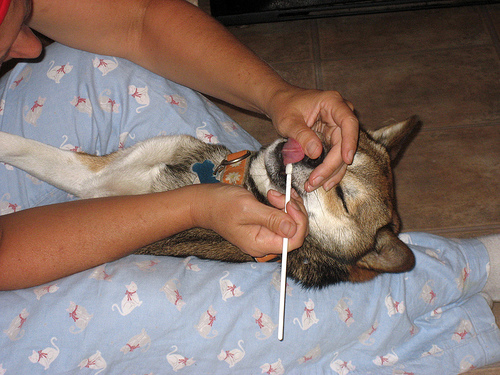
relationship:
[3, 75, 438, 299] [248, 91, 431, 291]
dog has head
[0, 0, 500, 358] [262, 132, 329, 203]
person cleaning teeth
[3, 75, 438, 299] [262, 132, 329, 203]
dog has teeth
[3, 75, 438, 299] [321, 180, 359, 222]
dog has eye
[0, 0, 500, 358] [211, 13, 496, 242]
person on top of floor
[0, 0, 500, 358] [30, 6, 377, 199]
person has hand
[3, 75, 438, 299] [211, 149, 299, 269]
dog has neck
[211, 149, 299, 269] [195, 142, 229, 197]
neck has dog tag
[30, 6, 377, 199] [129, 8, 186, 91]
arm has crease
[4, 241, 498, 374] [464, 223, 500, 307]
leg has sock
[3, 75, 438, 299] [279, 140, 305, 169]
dog has tounge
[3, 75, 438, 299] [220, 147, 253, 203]
dog has collar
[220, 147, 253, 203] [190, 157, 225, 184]
collar has dog tag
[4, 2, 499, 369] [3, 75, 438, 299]
person holding dog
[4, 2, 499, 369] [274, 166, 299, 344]
person holding q-tip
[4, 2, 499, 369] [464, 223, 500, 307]
person wearing sock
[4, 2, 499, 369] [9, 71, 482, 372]
person wearing pajama pants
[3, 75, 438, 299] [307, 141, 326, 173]
dog has nose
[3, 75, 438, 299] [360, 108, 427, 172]
dog has ear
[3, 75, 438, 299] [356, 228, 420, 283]
dog has ear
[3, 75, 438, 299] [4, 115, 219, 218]
dog has leg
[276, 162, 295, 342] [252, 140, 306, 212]
q-tip in mouth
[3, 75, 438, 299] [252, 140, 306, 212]
dog has mouth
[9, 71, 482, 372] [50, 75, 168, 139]
pajamas have cats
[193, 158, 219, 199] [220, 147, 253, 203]
bone on collar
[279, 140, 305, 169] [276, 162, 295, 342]
tounge licking q-tip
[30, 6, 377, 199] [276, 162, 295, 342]
hand holding q-tip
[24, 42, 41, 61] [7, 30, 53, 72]
top of nose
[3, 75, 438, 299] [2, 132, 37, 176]
dog has front paw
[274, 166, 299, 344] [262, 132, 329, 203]
q-tip cleaning teeth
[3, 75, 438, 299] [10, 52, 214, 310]
dog in lap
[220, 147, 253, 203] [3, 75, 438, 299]
collar on dog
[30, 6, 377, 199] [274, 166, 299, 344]
hand has q-tip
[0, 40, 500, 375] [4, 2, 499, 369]
pajama pants on female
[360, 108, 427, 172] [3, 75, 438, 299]
ear of dog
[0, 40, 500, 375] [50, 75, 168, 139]
pajama pants have cats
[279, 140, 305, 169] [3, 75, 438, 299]
tounge of dog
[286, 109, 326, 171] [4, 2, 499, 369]
finger of person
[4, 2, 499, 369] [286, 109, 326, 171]
person has finger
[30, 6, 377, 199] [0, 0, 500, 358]
hand of person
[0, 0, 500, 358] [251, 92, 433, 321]
person holding head